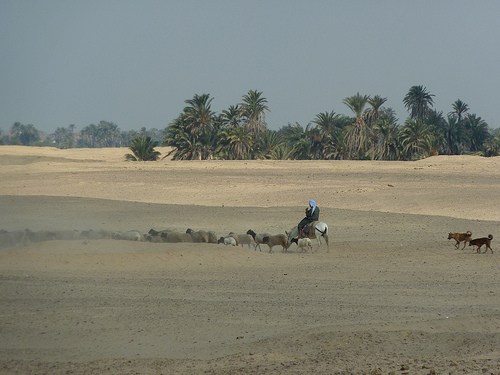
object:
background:
[0, 1, 499, 161]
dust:
[0, 220, 197, 256]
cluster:
[122, 72, 496, 165]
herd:
[0, 215, 335, 262]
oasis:
[0, 194, 498, 371]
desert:
[0, 143, 500, 373]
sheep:
[256, 230, 291, 253]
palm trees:
[161, 89, 220, 162]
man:
[301, 199, 326, 224]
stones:
[379, 360, 500, 374]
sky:
[0, 0, 495, 88]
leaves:
[160, 91, 219, 162]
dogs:
[463, 233, 497, 254]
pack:
[301, 225, 310, 237]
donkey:
[285, 215, 333, 250]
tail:
[318, 223, 330, 241]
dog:
[446, 231, 471, 251]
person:
[294, 199, 323, 232]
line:
[0, 81, 499, 161]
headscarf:
[305, 199, 321, 217]